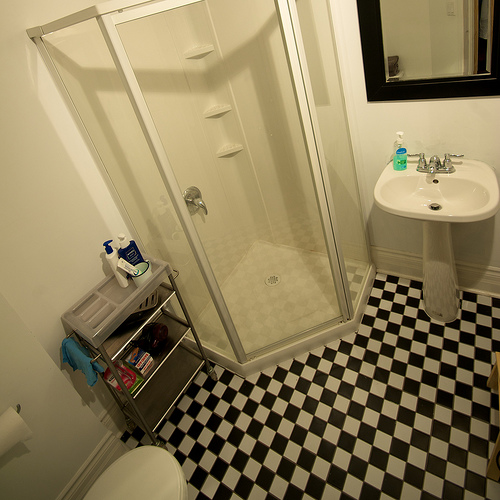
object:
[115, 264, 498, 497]
floor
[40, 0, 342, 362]
shower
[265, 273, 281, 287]
drainage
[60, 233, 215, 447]
bathroom caddy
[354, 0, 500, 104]
mirror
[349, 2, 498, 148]
wall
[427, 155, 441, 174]
faucet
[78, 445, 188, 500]
lid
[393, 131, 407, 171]
dispenser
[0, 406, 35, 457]
tissue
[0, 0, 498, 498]
shower room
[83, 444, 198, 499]
toilet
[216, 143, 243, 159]
shelf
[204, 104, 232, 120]
shelf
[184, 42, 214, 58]
shelf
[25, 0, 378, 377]
shower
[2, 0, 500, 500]
room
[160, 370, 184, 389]
trolley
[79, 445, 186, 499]
seat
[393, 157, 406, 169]
soap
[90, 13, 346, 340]
window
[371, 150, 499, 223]
sink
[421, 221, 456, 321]
pedestal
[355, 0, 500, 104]
frames